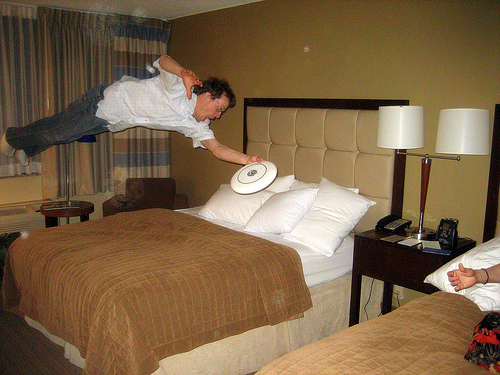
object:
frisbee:
[229, 160, 279, 196]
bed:
[0, 200, 388, 375]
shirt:
[93, 54, 216, 150]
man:
[0, 53, 266, 167]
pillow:
[281, 175, 379, 258]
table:
[347, 227, 480, 327]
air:
[38, 7, 325, 168]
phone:
[374, 213, 413, 236]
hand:
[244, 154, 269, 167]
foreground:
[4, 32, 354, 274]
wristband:
[175, 67, 187, 77]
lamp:
[374, 105, 424, 150]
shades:
[293, 107, 329, 150]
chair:
[101, 177, 191, 219]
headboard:
[241, 97, 416, 236]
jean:
[3, 82, 110, 159]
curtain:
[0, 6, 173, 137]